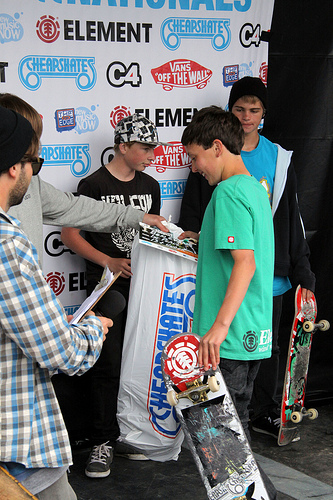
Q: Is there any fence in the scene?
A: No, there are no fences.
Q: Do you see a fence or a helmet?
A: No, there are no fences or helmets.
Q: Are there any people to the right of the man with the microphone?
A: Yes, there is a person to the right of the man.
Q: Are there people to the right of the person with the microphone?
A: Yes, there is a person to the right of the man.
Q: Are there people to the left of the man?
A: No, the person is to the right of the man.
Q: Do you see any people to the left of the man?
A: No, the person is to the right of the man.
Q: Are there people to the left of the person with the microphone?
A: No, the person is to the right of the man.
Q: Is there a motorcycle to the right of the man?
A: No, there is a person to the right of the man.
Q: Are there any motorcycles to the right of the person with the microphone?
A: No, there is a person to the right of the man.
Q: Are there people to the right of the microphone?
A: Yes, there is a person to the right of the microphone.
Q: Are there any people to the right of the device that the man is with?
A: Yes, there is a person to the right of the microphone.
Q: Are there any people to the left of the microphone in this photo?
A: No, the person is to the right of the microphone.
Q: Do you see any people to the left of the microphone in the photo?
A: No, the person is to the right of the microphone.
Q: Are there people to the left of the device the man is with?
A: No, the person is to the right of the microphone.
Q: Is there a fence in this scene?
A: No, there are no fences.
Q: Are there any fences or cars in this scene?
A: No, there are no fences or cars.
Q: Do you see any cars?
A: No, there are no cars.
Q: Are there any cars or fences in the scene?
A: No, there are no cars or fences.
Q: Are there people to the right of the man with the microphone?
A: Yes, there is a person to the right of the man.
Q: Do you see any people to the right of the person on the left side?
A: Yes, there is a person to the right of the man.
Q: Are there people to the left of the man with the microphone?
A: No, the person is to the right of the man.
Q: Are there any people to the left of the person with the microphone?
A: No, the person is to the right of the man.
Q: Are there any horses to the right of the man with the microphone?
A: No, there is a person to the right of the man.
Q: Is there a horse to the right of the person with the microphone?
A: No, there is a person to the right of the man.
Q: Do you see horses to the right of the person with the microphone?
A: No, there is a person to the right of the man.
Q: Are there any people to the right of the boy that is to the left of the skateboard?
A: No, the person is to the left of the boy.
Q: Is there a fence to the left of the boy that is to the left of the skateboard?
A: No, there is a person to the left of the boy.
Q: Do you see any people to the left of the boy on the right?
A: Yes, there is a person to the left of the boy.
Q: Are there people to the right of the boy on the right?
A: No, the person is to the left of the boy.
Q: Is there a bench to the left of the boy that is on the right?
A: No, there is a person to the left of the boy.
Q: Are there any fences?
A: No, there are no fences.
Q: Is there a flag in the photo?
A: No, there are no flags.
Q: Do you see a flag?
A: No, there are no flags.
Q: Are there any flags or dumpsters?
A: No, there are no flags or dumpsters.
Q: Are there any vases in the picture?
A: No, there are no vases.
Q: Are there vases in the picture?
A: No, there are no vases.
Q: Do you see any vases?
A: No, there are no vases.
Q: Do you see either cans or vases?
A: No, there are no vases or cans.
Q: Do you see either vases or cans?
A: No, there are no vases or cans.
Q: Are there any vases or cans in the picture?
A: No, there are no vases or cans.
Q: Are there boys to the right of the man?
A: Yes, there is a boy to the right of the man.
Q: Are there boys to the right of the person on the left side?
A: Yes, there is a boy to the right of the man.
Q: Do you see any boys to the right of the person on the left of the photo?
A: Yes, there is a boy to the right of the man.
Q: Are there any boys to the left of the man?
A: No, the boy is to the right of the man.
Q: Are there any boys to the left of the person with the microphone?
A: No, the boy is to the right of the man.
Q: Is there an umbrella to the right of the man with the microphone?
A: No, there is a boy to the right of the man.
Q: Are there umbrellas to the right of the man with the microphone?
A: No, there is a boy to the right of the man.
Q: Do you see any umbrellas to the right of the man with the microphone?
A: No, there is a boy to the right of the man.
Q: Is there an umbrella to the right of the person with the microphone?
A: No, there is a boy to the right of the man.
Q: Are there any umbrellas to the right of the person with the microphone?
A: No, there is a boy to the right of the man.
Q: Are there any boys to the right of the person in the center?
A: Yes, there is a boy to the right of the person.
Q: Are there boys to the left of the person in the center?
A: No, the boy is to the right of the person.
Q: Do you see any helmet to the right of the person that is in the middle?
A: No, there is a boy to the right of the person.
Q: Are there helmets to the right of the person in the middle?
A: No, there is a boy to the right of the person.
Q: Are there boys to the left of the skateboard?
A: Yes, there is a boy to the left of the skateboard.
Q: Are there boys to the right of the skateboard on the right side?
A: No, the boy is to the left of the skateboard.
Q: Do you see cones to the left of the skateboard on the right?
A: No, there is a boy to the left of the skateboard.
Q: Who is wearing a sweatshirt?
A: The boy is wearing a sweatshirt.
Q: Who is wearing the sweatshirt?
A: The boy is wearing a sweatshirt.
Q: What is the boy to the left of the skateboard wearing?
A: The boy is wearing a sweatshirt.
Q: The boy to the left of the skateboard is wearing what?
A: The boy is wearing a sweatshirt.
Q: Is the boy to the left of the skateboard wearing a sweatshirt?
A: Yes, the boy is wearing a sweatshirt.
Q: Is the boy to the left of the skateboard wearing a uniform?
A: No, the boy is wearing a sweatshirt.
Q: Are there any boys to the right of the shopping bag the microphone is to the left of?
A: Yes, there is a boy to the right of the shopping bag.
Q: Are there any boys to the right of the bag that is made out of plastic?
A: Yes, there is a boy to the right of the shopping bag.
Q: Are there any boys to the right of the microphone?
A: Yes, there is a boy to the right of the microphone.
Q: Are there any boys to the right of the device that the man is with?
A: Yes, there is a boy to the right of the microphone.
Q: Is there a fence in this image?
A: No, there are no fences.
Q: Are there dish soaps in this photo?
A: No, there are no dish soaps.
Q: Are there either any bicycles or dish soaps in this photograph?
A: No, there are no dish soaps or bicycles.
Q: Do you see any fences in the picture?
A: No, there are no fences.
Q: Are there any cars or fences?
A: No, there are no fences or cars.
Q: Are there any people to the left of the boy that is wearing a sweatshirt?
A: Yes, there are people to the left of the boy.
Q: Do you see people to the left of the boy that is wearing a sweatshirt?
A: Yes, there are people to the left of the boy.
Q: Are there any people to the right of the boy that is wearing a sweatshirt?
A: No, the people are to the left of the boy.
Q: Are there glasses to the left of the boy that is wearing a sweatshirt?
A: No, there are people to the left of the boy.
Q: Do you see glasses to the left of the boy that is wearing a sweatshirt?
A: No, there are people to the left of the boy.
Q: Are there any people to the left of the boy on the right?
A: Yes, there are people to the left of the boy.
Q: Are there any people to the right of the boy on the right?
A: No, the people are to the left of the boy.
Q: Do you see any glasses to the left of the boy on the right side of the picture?
A: No, there are people to the left of the boy.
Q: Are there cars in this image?
A: No, there are no cars.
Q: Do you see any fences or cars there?
A: No, there are no cars or fences.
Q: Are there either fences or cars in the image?
A: No, there are no cars or fences.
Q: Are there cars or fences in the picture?
A: No, there are no cars or fences.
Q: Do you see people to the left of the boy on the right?
A: Yes, there are people to the left of the boy.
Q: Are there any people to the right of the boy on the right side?
A: No, the people are to the left of the boy.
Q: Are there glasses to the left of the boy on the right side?
A: No, there are people to the left of the boy.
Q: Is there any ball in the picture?
A: No, there are no balls.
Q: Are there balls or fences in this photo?
A: No, there are no balls or fences.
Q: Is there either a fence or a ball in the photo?
A: No, there are no balls or fences.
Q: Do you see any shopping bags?
A: Yes, there is a shopping bag.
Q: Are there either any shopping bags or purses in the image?
A: Yes, there is a shopping bag.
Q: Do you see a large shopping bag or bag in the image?
A: Yes, there is a large shopping bag.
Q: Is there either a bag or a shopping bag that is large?
A: Yes, the shopping bag is large.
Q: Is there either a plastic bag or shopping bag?
A: Yes, there is a plastic shopping bag.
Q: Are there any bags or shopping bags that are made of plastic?
A: Yes, the shopping bag is made of plastic.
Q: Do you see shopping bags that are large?
A: Yes, there is a large shopping bag.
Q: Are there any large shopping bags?
A: Yes, there is a large shopping bag.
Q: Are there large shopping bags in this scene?
A: Yes, there is a large shopping bag.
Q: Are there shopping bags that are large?
A: Yes, there is a shopping bag that is large.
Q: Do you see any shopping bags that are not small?
A: Yes, there is a large shopping bag.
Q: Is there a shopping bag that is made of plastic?
A: Yes, there is a shopping bag that is made of plastic.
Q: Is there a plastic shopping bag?
A: Yes, there is a shopping bag that is made of plastic.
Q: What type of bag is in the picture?
A: The bag is a shopping bag.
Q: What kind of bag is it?
A: The bag is a shopping bag.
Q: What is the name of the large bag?
A: The bag is a shopping bag.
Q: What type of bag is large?
A: The bag is a shopping bag.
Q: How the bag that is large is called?
A: The bag is a shopping bag.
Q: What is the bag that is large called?
A: The bag is a shopping bag.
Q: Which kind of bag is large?
A: The bag is a shopping bag.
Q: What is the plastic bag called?
A: The bag is a shopping bag.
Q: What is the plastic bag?
A: The bag is a shopping bag.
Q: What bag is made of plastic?
A: The bag is a shopping bag.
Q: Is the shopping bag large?
A: Yes, the shopping bag is large.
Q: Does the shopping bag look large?
A: Yes, the shopping bag is large.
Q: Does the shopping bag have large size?
A: Yes, the shopping bag is large.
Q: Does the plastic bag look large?
A: Yes, the shopping bag is large.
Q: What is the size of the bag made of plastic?
A: The shopping bag is large.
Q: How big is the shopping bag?
A: The shopping bag is large.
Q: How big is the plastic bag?
A: The shopping bag is large.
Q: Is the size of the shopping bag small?
A: No, the shopping bag is large.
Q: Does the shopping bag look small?
A: No, the shopping bag is large.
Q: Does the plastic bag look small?
A: No, the shopping bag is large.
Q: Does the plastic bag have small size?
A: No, the shopping bag is large.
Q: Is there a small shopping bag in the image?
A: No, there is a shopping bag but it is large.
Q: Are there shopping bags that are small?
A: No, there is a shopping bag but it is large.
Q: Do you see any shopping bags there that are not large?
A: No, there is a shopping bag but it is large.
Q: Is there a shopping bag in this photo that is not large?
A: No, there is a shopping bag but it is large.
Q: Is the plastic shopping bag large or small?
A: The shopping bag is large.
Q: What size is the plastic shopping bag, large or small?
A: The shopping bag is large.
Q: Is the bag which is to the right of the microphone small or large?
A: The shopping bag is large.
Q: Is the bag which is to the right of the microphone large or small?
A: The shopping bag is large.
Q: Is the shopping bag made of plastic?
A: Yes, the shopping bag is made of plastic.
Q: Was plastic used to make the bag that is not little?
A: Yes, the shopping bag is made of plastic.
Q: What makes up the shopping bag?
A: The shopping bag is made of plastic.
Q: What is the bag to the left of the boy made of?
A: The shopping bag is made of plastic.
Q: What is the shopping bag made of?
A: The shopping bag is made of plastic.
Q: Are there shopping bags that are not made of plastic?
A: No, there is a shopping bag but it is made of plastic.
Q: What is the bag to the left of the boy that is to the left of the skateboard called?
A: The bag is a shopping bag.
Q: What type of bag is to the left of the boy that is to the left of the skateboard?
A: The bag is a shopping bag.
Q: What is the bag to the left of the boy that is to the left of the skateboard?
A: The bag is a shopping bag.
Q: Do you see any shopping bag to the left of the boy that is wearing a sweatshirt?
A: Yes, there is a shopping bag to the left of the boy.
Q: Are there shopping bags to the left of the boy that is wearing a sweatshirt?
A: Yes, there is a shopping bag to the left of the boy.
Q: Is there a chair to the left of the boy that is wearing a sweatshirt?
A: No, there is a shopping bag to the left of the boy.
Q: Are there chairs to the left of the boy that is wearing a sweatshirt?
A: No, there is a shopping bag to the left of the boy.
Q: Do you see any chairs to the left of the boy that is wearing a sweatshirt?
A: No, there is a shopping bag to the left of the boy.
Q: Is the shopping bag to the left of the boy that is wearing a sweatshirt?
A: Yes, the shopping bag is to the left of the boy.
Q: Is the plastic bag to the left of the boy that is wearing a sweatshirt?
A: Yes, the shopping bag is to the left of the boy.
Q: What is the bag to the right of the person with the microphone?
A: The bag is a shopping bag.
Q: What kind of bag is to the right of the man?
A: The bag is a shopping bag.